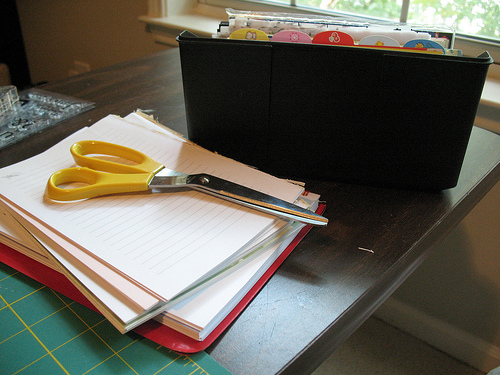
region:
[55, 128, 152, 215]
The yellow handle of the scissors.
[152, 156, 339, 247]
The blades of the scissors.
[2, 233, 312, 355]
The red folder beneath the pile of papers.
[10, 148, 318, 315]
The pile of papers on top of the red folder.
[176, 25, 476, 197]
The black bin to hold the papers.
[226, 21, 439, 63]
The divider tabs in the bin.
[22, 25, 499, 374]
The wooden table the items are located on.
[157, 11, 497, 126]
The windowsill of the window.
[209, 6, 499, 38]
The window in the room.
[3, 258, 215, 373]
The green graph and ruler plate on the left.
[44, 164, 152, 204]
orange handle on some scissors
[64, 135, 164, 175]
orange handle on some scissors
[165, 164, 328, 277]
metal blade on scissors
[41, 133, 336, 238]
a large pair of scissors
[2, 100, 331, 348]
stack of notebooks on a desk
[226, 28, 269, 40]
colored tab of a file folder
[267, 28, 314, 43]
colored tab of a file folder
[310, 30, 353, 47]
colored tab of a file folder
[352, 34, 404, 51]
colored tab of a file folder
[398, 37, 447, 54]
colored tab of a file folder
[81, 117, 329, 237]
Scissors on top of the notepad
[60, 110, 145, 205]
The scissors handle is yellow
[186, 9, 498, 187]
A filing box is on the table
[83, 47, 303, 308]
Paper on the table.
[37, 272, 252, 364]
A red book on the table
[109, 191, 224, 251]
Lines on the paper.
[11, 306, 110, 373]
A green ruler on the table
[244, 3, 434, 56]
Papers in the box.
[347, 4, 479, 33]
Trees on the outside of the window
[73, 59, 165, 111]
The table is brown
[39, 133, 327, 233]
yellow scissors laying down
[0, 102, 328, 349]
stack of white paper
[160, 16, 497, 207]
black organizer on the table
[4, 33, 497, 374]
dark brown wooden table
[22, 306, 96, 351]
green box with a yellow outline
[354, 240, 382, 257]
small white line on the table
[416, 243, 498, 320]
shadow on the wall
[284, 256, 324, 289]
shadow from the scissors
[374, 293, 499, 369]
white trim along the bottom of the wall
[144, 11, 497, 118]
white window ledge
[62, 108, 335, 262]
pair of yellow handled scissors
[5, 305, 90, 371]
a green plastic cutting mat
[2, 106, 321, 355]
a stack of papers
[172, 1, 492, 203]
an organizational file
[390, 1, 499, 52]
a window with a view outside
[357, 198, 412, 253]
a table used for crafting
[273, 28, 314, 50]
a pink tab on a divider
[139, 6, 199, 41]
a wooden window sill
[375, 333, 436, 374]
floor of the craft room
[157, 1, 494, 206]
a box full of craft ideas in dividers